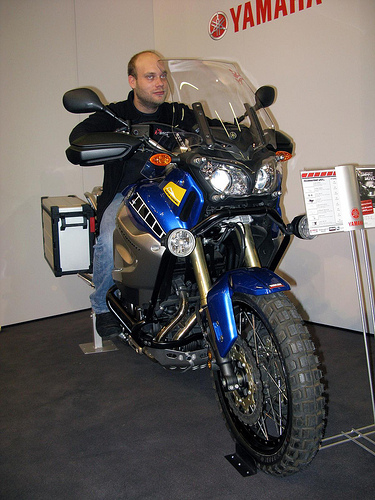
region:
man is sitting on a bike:
[50, 36, 332, 468]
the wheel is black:
[195, 276, 318, 483]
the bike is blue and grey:
[78, 149, 283, 352]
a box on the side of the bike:
[31, 191, 107, 289]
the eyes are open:
[137, 68, 172, 84]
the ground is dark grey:
[65, 381, 196, 489]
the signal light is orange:
[140, 147, 183, 168]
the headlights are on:
[180, 160, 286, 198]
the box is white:
[28, 182, 106, 281]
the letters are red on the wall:
[215, 1, 337, 34]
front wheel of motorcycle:
[189, 275, 339, 481]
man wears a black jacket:
[57, 52, 295, 325]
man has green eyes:
[92, 43, 213, 141]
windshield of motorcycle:
[162, 55, 277, 164]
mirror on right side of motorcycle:
[231, 71, 285, 127]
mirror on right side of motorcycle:
[56, 76, 131, 141]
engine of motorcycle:
[131, 267, 211, 357]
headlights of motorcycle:
[187, 146, 287, 201]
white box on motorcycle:
[34, 187, 98, 284]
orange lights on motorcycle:
[147, 147, 295, 173]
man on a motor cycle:
[19, 34, 354, 480]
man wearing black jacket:
[7, 45, 352, 476]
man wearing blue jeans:
[23, 36, 330, 471]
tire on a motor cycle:
[256, 301, 334, 481]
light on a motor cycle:
[157, 214, 199, 261]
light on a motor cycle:
[189, 151, 295, 208]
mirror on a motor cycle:
[58, 75, 106, 127]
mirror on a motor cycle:
[258, 75, 286, 113]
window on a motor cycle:
[165, 48, 271, 153]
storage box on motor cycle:
[28, 186, 91, 279]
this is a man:
[45, 35, 247, 326]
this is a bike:
[63, 28, 344, 492]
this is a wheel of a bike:
[200, 258, 335, 479]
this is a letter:
[221, 0, 244, 38]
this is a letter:
[238, 0, 257, 33]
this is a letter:
[257, 0, 273, 25]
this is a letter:
[271, 0, 288, 21]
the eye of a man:
[144, 68, 157, 89]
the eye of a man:
[158, 69, 173, 85]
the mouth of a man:
[149, 85, 170, 102]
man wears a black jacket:
[45, 40, 342, 485]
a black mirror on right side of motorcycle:
[228, 73, 278, 137]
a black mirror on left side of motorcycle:
[50, 77, 130, 134]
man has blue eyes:
[97, 41, 197, 140]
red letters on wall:
[199, 0, 357, 46]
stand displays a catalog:
[289, 157, 373, 451]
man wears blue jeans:
[63, 39, 237, 339]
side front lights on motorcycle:
[158, 208, 320, 273]